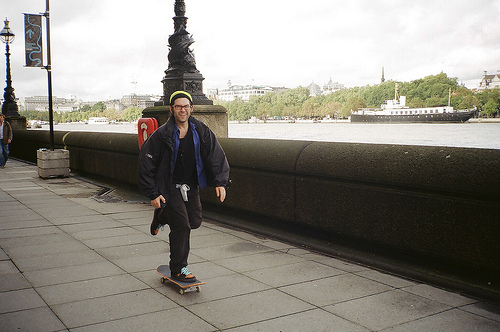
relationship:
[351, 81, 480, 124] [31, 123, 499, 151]
boat in water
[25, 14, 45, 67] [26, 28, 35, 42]
lines with arrow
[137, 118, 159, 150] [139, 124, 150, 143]
object with white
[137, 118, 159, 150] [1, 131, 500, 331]
object on bridge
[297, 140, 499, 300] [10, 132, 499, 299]
part of wall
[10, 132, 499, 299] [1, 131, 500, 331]
wall of bridge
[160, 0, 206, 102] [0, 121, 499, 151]
statue on edge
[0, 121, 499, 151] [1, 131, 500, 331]
edge of bridge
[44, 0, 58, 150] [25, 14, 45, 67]
pole with flag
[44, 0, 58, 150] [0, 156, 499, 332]
pole on walkway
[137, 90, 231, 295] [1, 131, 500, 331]
man on bridge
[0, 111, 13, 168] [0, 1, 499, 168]
person in background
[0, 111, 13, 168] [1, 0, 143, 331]
person on left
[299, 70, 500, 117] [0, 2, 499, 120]
trees in distance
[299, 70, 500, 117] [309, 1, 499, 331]
trees on right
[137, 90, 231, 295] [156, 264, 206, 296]
man on skateboard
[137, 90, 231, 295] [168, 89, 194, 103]
man wearing beanie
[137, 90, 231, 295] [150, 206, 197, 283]
man wearing sneakers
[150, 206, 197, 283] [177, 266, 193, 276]
sneakers have laces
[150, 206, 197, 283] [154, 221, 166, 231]
sneakers have laces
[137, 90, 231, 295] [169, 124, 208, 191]
man wearing shirt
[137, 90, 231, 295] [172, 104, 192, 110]
man wearing eyeglasses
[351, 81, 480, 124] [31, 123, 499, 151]
boat on water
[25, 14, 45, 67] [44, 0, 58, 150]
flag on post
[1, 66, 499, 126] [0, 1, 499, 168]
buildings in background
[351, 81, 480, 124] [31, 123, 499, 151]
boat on river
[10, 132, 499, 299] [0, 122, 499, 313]
wall between sidewalk and river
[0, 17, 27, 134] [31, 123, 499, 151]
light along river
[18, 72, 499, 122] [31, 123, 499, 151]
trees lining river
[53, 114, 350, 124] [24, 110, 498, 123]
boats along shore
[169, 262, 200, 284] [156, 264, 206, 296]
foot on skateboard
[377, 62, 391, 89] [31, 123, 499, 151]
tower across river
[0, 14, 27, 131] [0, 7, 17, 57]
light on top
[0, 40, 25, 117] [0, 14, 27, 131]
pole with light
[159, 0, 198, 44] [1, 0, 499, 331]
lamp not visible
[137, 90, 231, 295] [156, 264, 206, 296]
man riding skateboard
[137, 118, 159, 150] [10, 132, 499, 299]
square on wall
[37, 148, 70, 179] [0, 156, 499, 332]
box on sidewalk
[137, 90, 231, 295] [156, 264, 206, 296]
skater has board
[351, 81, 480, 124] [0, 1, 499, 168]
ship in background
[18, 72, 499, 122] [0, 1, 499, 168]
trees in background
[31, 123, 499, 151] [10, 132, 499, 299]
river behind wall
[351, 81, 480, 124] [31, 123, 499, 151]
ship on canal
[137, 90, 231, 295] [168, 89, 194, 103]
man wearing cap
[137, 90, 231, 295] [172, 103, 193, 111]
man wearing eyeglasses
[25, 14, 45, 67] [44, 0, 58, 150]
banner on pole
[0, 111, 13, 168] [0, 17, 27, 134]
person near post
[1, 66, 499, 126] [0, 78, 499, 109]
buildings on hills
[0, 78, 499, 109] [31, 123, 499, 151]
hills across canal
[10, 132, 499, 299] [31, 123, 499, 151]
wall along canal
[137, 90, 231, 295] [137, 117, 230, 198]
man wearing jacket